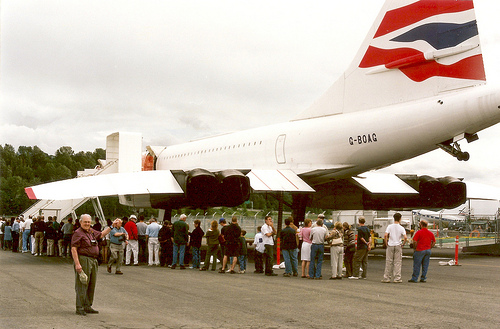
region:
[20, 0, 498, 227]
an airplane on display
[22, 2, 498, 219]
the airplane is white, red and blue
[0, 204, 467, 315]
a group of people standing outside the airplane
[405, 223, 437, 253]
the man is wearing a red shirt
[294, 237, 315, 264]
the woman is wearing a white skirt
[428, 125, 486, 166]
a set of wheels coming from the tail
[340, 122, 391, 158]
black lettering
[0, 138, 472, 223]
a cluster of trees behind the airplane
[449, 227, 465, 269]
an orange caution pole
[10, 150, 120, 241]
steps entering airplane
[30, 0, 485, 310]
Picture of people waiting in line at airplane.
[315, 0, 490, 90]
The tail of an airplane.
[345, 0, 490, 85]
Red, blue and white painted on tail of plane.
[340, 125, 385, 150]
Letters painted on plane.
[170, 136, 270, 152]
Passenger windows on plane.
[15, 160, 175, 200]
Left wing of airplane.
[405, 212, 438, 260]
An orange short sleeve shirt.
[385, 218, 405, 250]
A white short sleeve shirt.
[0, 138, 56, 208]
Green trees on left in background.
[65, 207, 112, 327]
An older man with cap in hand.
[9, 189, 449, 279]
crowd waiting to board aircraft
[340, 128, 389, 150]
aircraft identification numbers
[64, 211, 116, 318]
man pointing at aircraft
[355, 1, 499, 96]
red and blue painted on tail wing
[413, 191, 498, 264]
chain link fence behind aircraft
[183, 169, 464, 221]
four jet engines on wings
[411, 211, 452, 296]
man wearing red shirt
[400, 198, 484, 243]
aircraft beyond the fence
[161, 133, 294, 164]
passenger windows on fuselage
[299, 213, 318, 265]
woman wearing white skirt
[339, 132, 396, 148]
Number of the plane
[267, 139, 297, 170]
Emergency exit of plane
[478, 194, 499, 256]
Fencing of airport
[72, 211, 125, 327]
Old man waving at photographer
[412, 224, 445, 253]
Red shirt of a man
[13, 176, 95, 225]
Stairs to the plane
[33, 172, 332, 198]
The wind of the plane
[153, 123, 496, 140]
Body of the plane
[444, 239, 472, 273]
Orange cone on runway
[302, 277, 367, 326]
part of a runway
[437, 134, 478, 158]
part of some hind wheels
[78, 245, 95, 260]
part of a shirt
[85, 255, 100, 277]
part of a green trouser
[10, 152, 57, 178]
part of some trees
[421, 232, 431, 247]
part of a red top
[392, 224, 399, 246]
part of a white top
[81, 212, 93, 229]
face of an old man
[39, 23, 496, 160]
red white and blue plane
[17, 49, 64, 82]
white clouds in blue sky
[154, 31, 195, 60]
white clouds in blue sky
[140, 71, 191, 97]
white clouds in blue sky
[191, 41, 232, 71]
white clouds in blue sky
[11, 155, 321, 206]
The wing of a plane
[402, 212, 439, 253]
Man wearing a red shirt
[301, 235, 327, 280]
A pair of blue jeans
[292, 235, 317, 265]
A white colored skirt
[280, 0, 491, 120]
The tail of an airplane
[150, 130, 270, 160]
Small windows on side of plane